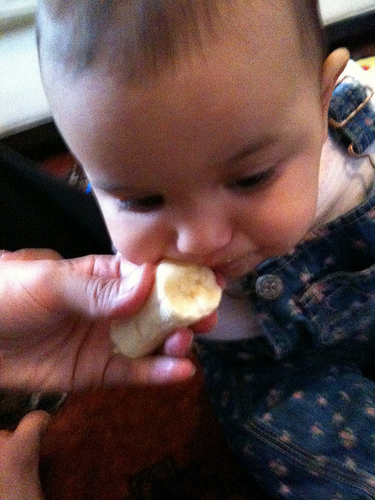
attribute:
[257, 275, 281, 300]
button — round, metal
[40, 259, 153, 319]
thumb — thick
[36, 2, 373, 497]
baby — eating, small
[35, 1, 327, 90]
hair — very fine, wispy, brown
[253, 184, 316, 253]
cheek — small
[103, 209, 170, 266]
cheek — small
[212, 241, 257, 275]
mouth — small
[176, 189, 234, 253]
nose — small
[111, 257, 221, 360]
banana — mushy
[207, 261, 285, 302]
clasp — metal